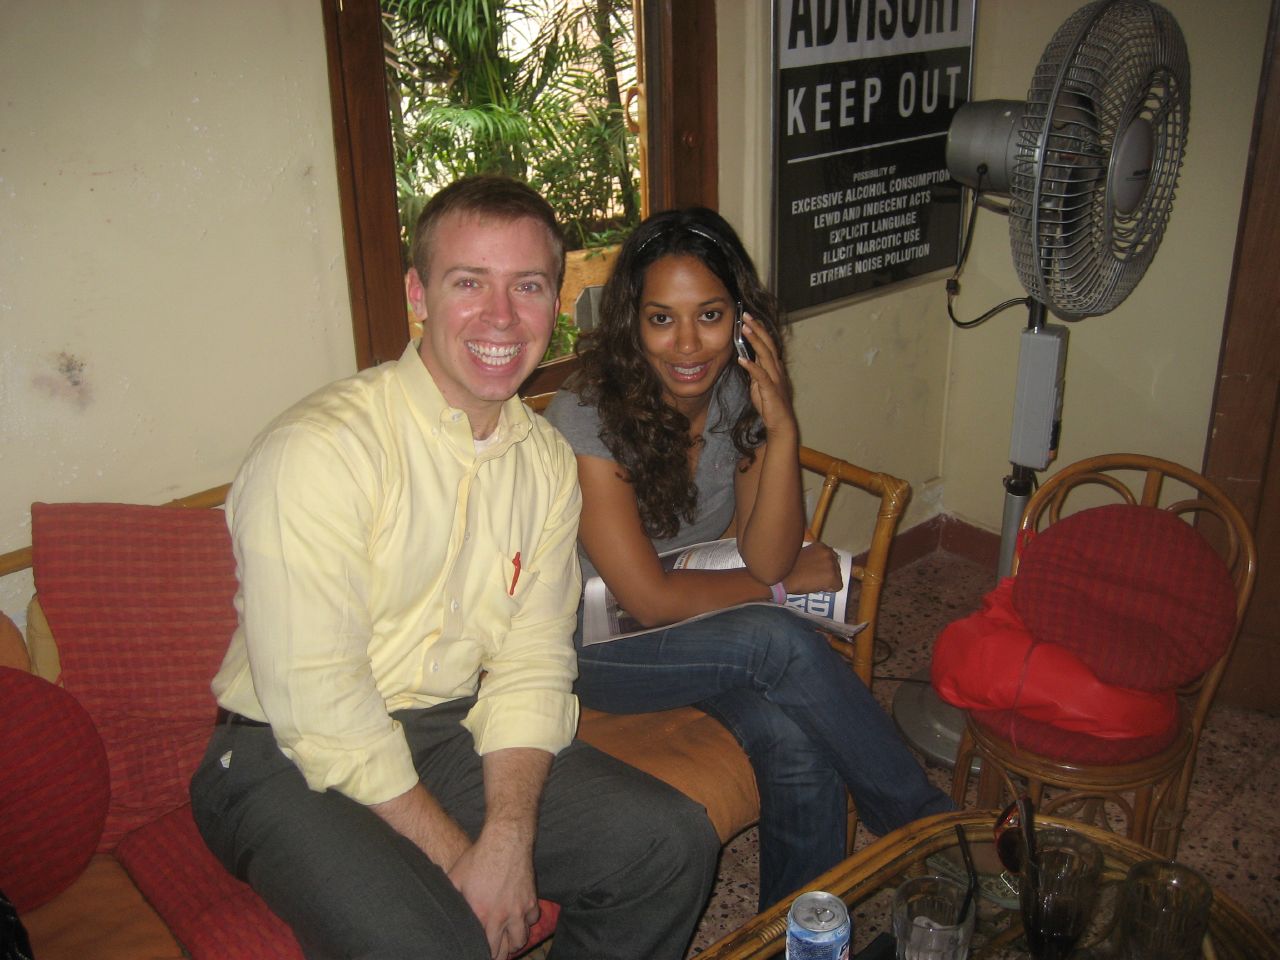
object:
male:
[193, 170, 727, 960]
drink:
[784, 891, 855, 960]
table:
[697, 809, 1274, 960]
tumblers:
[1018, 829, 1107, 960]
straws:
[953, 824, 977, 924]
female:
[544, 202, 1024, 940]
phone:
[733, 298, 757, 364]